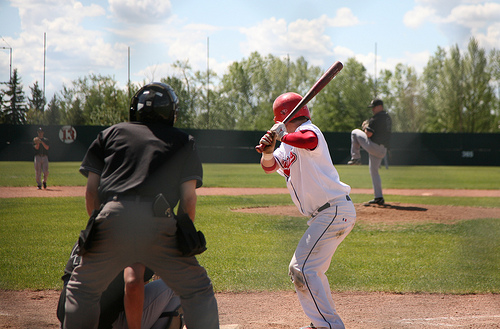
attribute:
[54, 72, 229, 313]
umpire — crouched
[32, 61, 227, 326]
umpire — for baseball game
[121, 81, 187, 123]
hat —  protective,  head's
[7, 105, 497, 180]
green fence —  Tall,  green,  of baseball diamond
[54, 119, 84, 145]
logo —  baseball's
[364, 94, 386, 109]
hat —   Pitcher's ,  black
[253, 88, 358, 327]
batter — waiting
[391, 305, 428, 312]
patch —  bare,  ground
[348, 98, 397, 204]
pitcher — throwing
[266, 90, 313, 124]
helmet — red, plastic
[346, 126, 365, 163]
leg —  up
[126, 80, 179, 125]
helmet — shiny, black, plastic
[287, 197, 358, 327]
pants —  for Baseball,  with dirt stains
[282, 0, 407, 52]
sky — light blue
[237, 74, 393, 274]
player —  for baseball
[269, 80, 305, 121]
helmet —  red,  Player's 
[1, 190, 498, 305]
green grass —  Green,  mowed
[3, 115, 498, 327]
field — for ball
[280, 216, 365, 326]
pants — white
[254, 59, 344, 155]
bat —  wood,  for Baseball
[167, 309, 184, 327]
protection —  shin's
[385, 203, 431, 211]
shadow —  of pitcher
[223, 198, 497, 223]
mound —   Pitcher's ,  of dirt,  pitcher's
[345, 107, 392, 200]
uniform —  gray and black,  pitcher's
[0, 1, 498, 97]
cloud — white